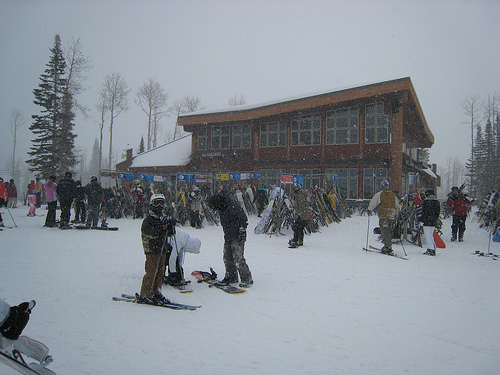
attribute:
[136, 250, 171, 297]
pants — brown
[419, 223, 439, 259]
pants — white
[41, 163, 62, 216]
jacket — pink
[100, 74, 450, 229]
ski lodge — brown, wooden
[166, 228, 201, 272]
jacket — white 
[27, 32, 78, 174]
evergreen tree — tall 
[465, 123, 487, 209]
evergreen tree — tall 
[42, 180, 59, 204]
jacket — pink , white 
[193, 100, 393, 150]
windows — large, angular 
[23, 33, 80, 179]
tree — large, evergreen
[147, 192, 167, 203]
helmet — white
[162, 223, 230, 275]
jacket — white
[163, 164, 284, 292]
jacket — snow jacket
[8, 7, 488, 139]
snowy sky — hazy , gray , snowy 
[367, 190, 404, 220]
jacket — white, brown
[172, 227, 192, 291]
pole — blue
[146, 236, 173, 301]
pole — blue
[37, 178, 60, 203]
jacket — pink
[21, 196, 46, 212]
snow gear — pink 